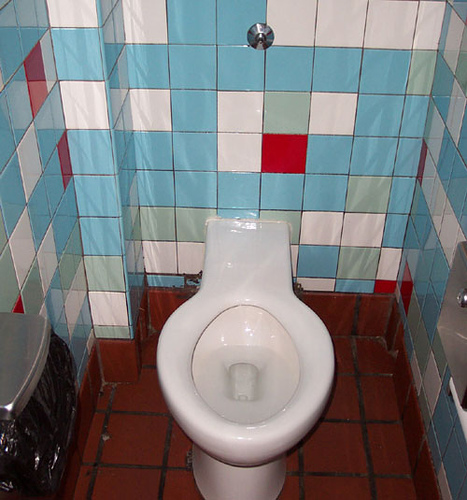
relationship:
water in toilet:
[199, 342, 292, 420] [156, 216, 338, 500]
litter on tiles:
[99, 430, 110, 442] [55, 287, 441, 500]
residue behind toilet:
[178, 277, 203, 302] [156, 216, 338, 500]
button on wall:
[244, 22, 275, 53] [2, 3, 463, 496]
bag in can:
[1, 335, 77, 498] [1, 313, 53, 411]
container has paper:
[432, 241, 466, 408] [448, 380, 467, 438]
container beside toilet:
[432, 241, 466, 408] [156, 216, 338, 500]